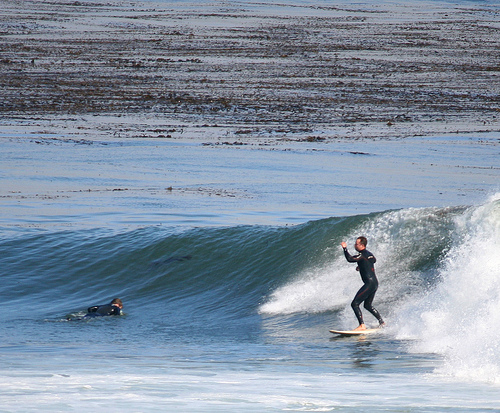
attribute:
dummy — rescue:
[68, 292, 125, 322]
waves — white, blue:
[175, 203, 499, 365]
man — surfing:
[342, 234, 384, 336]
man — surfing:
[76, 295, 126, 317]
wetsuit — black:
[351, 251, 380, 324]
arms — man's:
[339, 238, 383, 264]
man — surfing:
[337, 232, 386, 332]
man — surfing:
[61, 292, 125, 327]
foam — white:
[448, 243, 495, 295]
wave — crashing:
[383, 199, 498, 331]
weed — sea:
[71, 178, 233, 199]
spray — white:
[283, 210, 498, 386]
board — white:
[328, 327, 380, 334]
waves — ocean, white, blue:
[80, 202, 498, 364]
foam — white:
[437, 236, 497, 383]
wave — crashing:
[0, 197, 497, 375]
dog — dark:
[92, 266, 194, 331]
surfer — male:
[341, 234, 388, 331]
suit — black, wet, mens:
[327, 232, 393, 350]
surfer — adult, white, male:
[336, 227, 391, 334]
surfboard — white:
[331, 318, 398, 337]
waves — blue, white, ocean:
[413, 208, 488, 299]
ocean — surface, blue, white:
[2, 1, 484, 411]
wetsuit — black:
[343, 248, 383, 325]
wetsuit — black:
[80, 302, 122, 317]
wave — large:
[0, 202, 476, 321]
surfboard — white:
[329, 326, 380, 339]